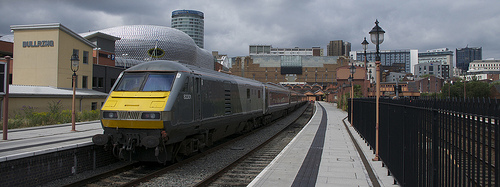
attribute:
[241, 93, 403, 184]
sidewalk — concrete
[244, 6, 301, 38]
sky — dark, cloudy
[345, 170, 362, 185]
brick — white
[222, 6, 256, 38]
sky — blue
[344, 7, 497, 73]
cloud — white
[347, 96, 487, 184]
gate — metal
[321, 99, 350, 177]
brick — white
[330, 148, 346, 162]
brick — white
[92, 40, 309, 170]
train — yellow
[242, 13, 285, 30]
clouds — white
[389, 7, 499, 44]
sky — blue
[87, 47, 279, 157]
train — yellow, gray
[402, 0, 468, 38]
sky — blue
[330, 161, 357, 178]
brick — white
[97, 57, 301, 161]
train — gray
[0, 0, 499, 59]
sky — blue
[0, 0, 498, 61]
clouds — white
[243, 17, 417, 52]
sky — cloudy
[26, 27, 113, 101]
building — beige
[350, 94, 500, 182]
fence — black, painted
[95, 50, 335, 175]
train — Gray 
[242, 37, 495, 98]
buildings — city buildings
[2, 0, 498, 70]
clouds — white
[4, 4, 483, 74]
clouds — grey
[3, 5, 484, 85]
sky — blue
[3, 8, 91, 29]
clouds — white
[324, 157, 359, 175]
brick — white